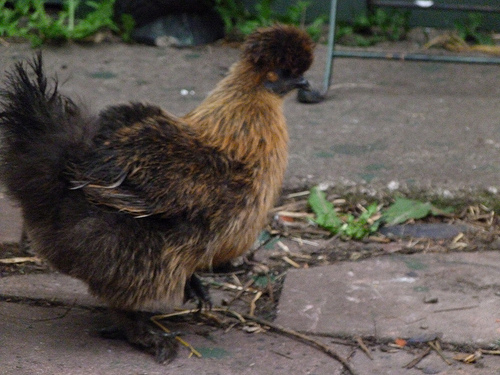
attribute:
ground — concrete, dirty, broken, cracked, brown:
[1, 35, 498, 374]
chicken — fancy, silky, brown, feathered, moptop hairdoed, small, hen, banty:
[2, 23, 314, 333]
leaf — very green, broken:
[309, 187, 381, 242]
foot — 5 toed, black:
[102, 302, 180, 361]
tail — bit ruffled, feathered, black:
[1, 53, 87, 237]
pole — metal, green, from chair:
[323, 1, 341, 94]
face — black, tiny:
[275, 63, 309, 95]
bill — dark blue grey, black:
[292, 78, 309, 90]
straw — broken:
[153, 300, 254, 354]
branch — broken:
[233, 307, 353, 370]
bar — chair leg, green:
[333, 44, 498, 69]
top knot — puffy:
[253, 22, 313, 69]